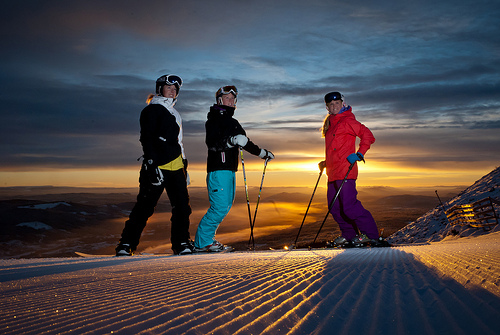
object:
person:
[111, 73, 198, 258]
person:
[188, 85, 275, 254]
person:
[317, 90, 376, 249]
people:
[113, 69, 394, 257]